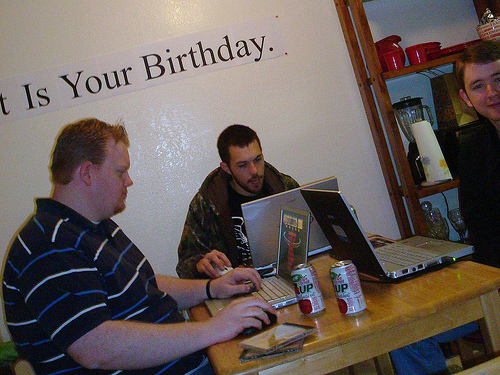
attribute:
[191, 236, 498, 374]
table — wooden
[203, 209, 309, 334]
laptop — on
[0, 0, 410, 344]
wall — shiny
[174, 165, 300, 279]
jacket — camouflage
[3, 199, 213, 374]
shirt — striped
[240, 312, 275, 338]
mouse — black